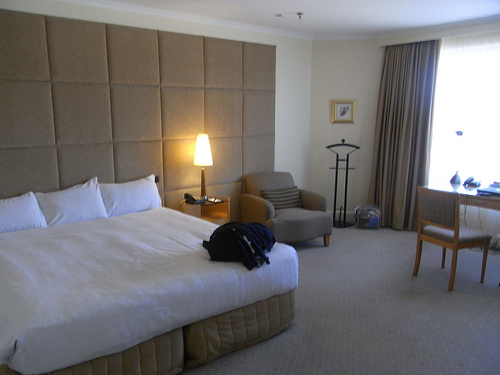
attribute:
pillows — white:
[5, 175, 162, 232]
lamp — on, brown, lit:
[186, 129, 215, 199]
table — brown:
[177, 186, 235, 223]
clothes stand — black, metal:
[323, 136, 356, 230]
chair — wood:
[412, 180, 493, 292]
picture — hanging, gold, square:
[328, 96, 358, 127]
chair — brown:
[238, 166, 339, 251]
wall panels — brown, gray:
[3, 2, 279, 235]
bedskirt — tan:
[28, 286, 306, 375]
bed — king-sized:
[3, 169, 301, 374]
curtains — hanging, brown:
[368, 36, 439, 238]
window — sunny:
[422, 31, 499, 194]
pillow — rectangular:
[259, 179, 307, 210]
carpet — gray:
[170, 210, 495, 374]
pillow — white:
[32, 177, 112, 228]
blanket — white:
[4, 198, 297, 373]